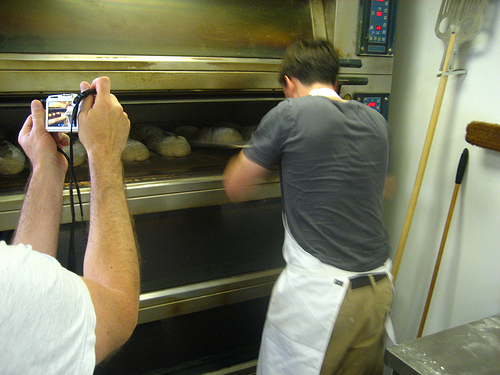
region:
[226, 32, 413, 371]
A man in a white apron using a oven.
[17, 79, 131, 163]
a persons hands holding a camera.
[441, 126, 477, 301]
a broom handle leaning on a wall.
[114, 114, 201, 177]
items baking in the oven.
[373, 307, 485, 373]
a dirty counter.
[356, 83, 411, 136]
a light on the oven controls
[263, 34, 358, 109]
a mans head.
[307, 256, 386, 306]
a man is wearing khaki pants with a brown belt.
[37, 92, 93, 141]
a picture on the camera's view finder.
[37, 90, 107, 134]
The man is taking a picture of the baking bread.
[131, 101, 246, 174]
Baking bread is in the oven.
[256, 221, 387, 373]
The man is wearing an apron.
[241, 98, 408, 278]
The man is wearing a gray shirt.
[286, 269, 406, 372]
The man is wearing tan pants.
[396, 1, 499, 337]
Baking utensils are leaning against the wall.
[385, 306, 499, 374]
The table has flour on it.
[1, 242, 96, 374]
This man's shirt is white.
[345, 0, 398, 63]
These are the controls for the oven.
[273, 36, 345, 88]
The man's hair is brown.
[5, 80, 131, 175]
A digital camera.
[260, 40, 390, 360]
A man baking bread.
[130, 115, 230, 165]
Bread in an oven.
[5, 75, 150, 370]
A person taking a picture.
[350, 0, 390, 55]
The buttons for the oven.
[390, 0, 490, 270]
A plastic and metal pizza peel.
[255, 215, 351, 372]
A white apron.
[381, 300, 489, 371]
The corner of a table.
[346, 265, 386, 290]
The baker's brown belt.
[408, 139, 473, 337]
A brown broomstick.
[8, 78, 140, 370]
Man taking picture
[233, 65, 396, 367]
Man cooking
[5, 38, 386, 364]
Two men in the kitchen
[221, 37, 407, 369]
Man wearing an apron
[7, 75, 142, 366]
Man holding a camera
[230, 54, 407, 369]
Man looking at a stove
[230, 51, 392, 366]
Man baking loaves of bread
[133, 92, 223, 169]
Bread in an oven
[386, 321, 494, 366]
Edge of kitchen table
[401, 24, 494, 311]
Cleaning items leaning against wall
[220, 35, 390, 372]
man in a white apron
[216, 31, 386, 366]
man at a commercial oven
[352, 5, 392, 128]
controls for an oven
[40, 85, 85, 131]
phone used as a camera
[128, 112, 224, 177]
items in a oven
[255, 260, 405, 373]
khakis with a belt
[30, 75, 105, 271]
strap on a phone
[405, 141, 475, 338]
pole against a wall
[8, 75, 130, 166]
snapping a photo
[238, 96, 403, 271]
a gray t-shirt